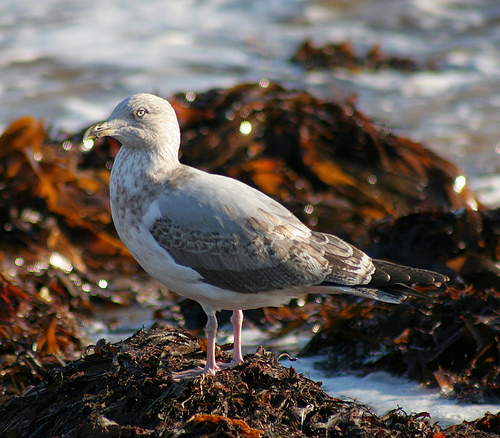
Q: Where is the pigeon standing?
A: On wet leaves.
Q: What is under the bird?
A: Leaves.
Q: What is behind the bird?
A: Piles of leaves.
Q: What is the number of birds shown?
A: 1.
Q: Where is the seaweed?
A: Ground.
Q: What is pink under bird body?
A: Legs.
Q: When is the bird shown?
A: Sunny day.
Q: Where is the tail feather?
A: Back of bird.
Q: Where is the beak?
A: Bird's face.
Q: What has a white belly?
A: Bird.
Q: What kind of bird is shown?
A: Seagull.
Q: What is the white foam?
A: Ocean water.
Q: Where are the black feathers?
A: Tail.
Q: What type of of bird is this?
A: It is a seagull.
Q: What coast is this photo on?
A: East Coast.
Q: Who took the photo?
A: Jackson Mingus.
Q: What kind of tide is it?
A: Very rough.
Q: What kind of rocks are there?
A: Mossy.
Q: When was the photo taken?
A: Daytime.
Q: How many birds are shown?
A: One.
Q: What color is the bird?
A: White, gray, and black.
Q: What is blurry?
A: Background.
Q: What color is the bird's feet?
A: Peach.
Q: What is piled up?
A: Leaves.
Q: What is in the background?
A: Water.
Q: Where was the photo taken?
A: At the beach.